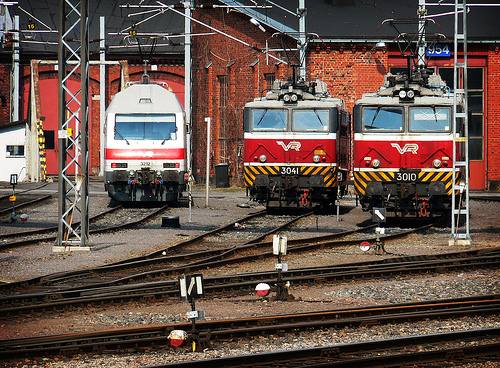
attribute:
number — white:
[275, 159, 325, 189]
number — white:
[270, 147, 306, 185]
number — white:
[273, 160, 310, 203]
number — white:
[383, 157, 426, 188]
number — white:
[390, 167, 424, 193]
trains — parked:
[100, 55, 483, 251]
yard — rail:
[20, 23, 485, 234]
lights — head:
[250, 139, 333, 181]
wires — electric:
[108, 13, 170, 66]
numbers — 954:
[416, 35, 465, 70]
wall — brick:
[322, 54, 417, 103]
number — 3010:
[391, 164, 435, 198]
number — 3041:
[253, 148, 322, 188]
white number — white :
[395, 164, 411, 184]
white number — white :
[403, 167, 412, 191]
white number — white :
[405, 170, 413, 183]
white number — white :
[408, 171, 416, 184]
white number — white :
[277, 167, 282, 177]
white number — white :
[286, 161, 293, 174]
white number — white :
[291, 164, 304, 177]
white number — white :
[291, 166, 297, 183]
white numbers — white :
[387, 158, 429, 193]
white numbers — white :
[275, 164, 300, 177]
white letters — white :
[270, 137, 304, 157]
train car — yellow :
[349, 55, 463, 228]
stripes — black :
[345, 164, 460, 204]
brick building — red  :
[264, 33, 496, 229]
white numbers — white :
[389, 164, 414, 184]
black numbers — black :
[147, 153, 173, 176]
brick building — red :
[191, 0, 492, 173]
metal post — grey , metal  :
[46, 0, 95, 260]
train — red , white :
[104, 76, 188, 206]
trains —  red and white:
[232, 134, 427, 252]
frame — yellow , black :
[224, 144, 337, 176]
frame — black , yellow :
[354, 156, 473, 213]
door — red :
[28, 48, 82, 193]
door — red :
[86, 64, 137, 214]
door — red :
[289, 39, 406, 212]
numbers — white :
[60, 80, 91, 178]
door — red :
[38, 45, 166, 249]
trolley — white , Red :
[332, 170, 480, 280]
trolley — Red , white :
[322, 161, 436, 268]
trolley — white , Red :
[346, 156, 461, 291]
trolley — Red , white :
[319, 144, 479, 312]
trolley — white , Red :
[329, 141, 437, 261]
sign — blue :
[407, 28, 464, 73]